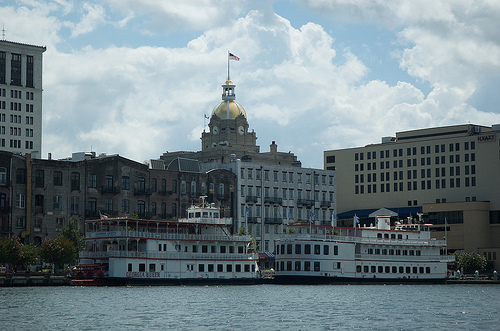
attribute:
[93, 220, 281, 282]
boat — ferry, white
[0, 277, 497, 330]
water — glistening, blue, mesmerizig, serene, tranquil, ripply, wavy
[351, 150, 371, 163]
window — double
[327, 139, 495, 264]
building — concrete, tan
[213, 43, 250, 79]
flag — flying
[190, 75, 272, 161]
building — tall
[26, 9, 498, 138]
sky — cloudy, blue